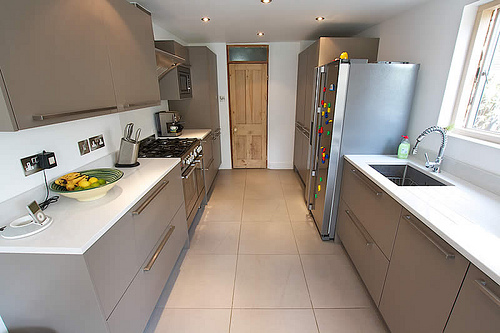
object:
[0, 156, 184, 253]
counter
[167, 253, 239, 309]
tiles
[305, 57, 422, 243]
refrigerator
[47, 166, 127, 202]
bowl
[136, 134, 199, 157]
oven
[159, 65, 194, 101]
microwave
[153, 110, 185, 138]
maker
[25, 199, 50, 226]
player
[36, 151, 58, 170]
charger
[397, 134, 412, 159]
detergent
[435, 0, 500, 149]
window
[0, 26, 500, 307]
kitchen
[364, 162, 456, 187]
sink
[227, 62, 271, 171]
door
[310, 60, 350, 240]
steel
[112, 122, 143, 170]
set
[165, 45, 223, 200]
pantry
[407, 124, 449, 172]
faucet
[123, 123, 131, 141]
knives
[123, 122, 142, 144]
top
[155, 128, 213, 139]
countertop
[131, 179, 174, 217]
handle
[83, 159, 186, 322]
drawer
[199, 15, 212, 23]
light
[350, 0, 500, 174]
wall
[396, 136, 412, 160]
bottle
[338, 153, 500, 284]
countertop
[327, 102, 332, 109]
magnets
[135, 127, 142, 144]
knife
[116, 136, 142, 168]
holder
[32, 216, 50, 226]
stand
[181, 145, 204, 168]
range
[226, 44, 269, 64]
transom